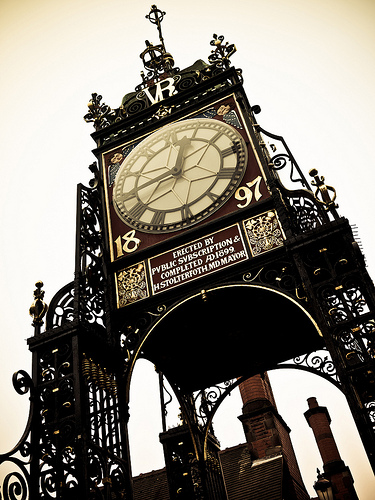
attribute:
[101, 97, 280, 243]
clock — large, circle, gold, ontop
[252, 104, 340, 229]
metal — scrolling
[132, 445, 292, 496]
roof — shingled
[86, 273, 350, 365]
arch — half circle, metal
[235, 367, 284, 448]
steeple — brick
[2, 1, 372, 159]
sky — hazy, cloudless, white, cloudy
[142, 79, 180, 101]
initials — silver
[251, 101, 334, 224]
scrolling — decorative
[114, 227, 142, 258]
numbers — grayish brown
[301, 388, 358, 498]
building — brick, tall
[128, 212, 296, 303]
plaque — below, mounted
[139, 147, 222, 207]
star — decorative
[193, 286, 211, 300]
knob — gold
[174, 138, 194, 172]
hand — gold, black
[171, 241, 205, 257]
errected — word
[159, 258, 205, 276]
completed — word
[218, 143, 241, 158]
numerals — roman, black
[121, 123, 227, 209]
face — large, white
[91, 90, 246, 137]
trim — black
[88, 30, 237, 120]
filigree — iron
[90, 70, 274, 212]
framing — black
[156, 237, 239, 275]
writing — white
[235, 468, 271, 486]
shingles — brown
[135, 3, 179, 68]
design — metal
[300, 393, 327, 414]
chimney — brown